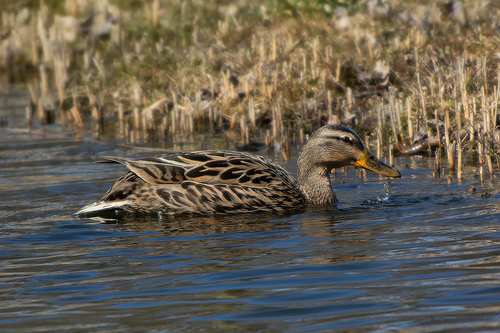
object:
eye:
[341, 135, 350, 143]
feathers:
[185, 165, 221, 179]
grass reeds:
[1, 0, 499, 201]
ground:
[0, 0, 500, 333]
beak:
[351, 149, 401, 179]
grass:
[0, 0, 500, 179]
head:
[297, 122, 400, 178]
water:
[0, 130, 499, 331]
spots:
[205, 152, 226, 158]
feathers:
[202, 159, 229, 170]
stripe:
[320, 129, 357, 141]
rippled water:
[158, 264, 295, 325]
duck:
[70, 122, 404, 220]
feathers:
[218, 166, 247, 181]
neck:
[296, 156, 340, 204]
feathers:
[250, 174, 274, 185]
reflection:
[72, 206, 374, 240]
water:
[2, 203, 500, 333]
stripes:
[319, 135, 355, 145]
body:
[71, 146, 303, 220]